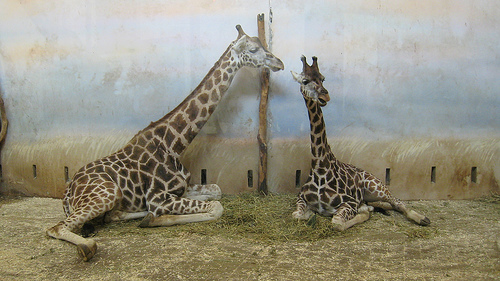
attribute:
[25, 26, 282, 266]
giraffe — laying down, larger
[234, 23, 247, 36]
horns — brown, black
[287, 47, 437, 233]
giraffe — laying on, looking, young, white, brown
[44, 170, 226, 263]
legs — folded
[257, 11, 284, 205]
wood — small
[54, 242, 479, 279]
ground — hay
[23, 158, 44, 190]
hole — small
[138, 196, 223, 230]
leg — white, bent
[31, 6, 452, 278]
giraffe — orange and white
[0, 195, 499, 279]
floor — brown, dirt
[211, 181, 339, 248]
hay — piled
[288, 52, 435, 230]
griaffe — brown, white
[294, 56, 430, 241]
giraffe — laying, smaller, laying down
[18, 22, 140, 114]
wall — large, concrete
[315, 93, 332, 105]
mouth — small, open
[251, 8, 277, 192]
pole — brown, wooden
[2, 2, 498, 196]
wall — cement, behiind, brown, blue, painted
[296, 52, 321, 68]
horns — black, brown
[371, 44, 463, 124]
wall — holed, foundation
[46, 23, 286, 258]
giraffe — brown, white, big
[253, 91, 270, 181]
wood — behind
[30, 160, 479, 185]
lines — dotted, black